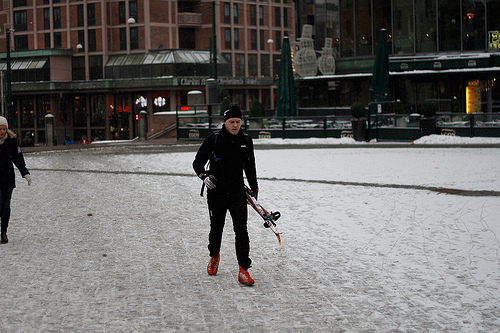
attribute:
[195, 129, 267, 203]
shirt — black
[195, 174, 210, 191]
gloves — black and white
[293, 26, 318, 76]
decoration — white, christmas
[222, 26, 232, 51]
window — white frame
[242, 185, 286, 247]
black ski — black 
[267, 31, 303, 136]
umbrella — unopened 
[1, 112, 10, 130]
cap — white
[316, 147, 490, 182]
snow — white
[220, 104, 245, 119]
hat — black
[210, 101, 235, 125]
hat — black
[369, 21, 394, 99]
umbrella — green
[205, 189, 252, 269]
pants — black 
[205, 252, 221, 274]
shoe — orange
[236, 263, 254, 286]
shoe — orange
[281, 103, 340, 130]
fence — black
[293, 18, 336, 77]
snowmen — white 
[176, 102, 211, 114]
sign — neon